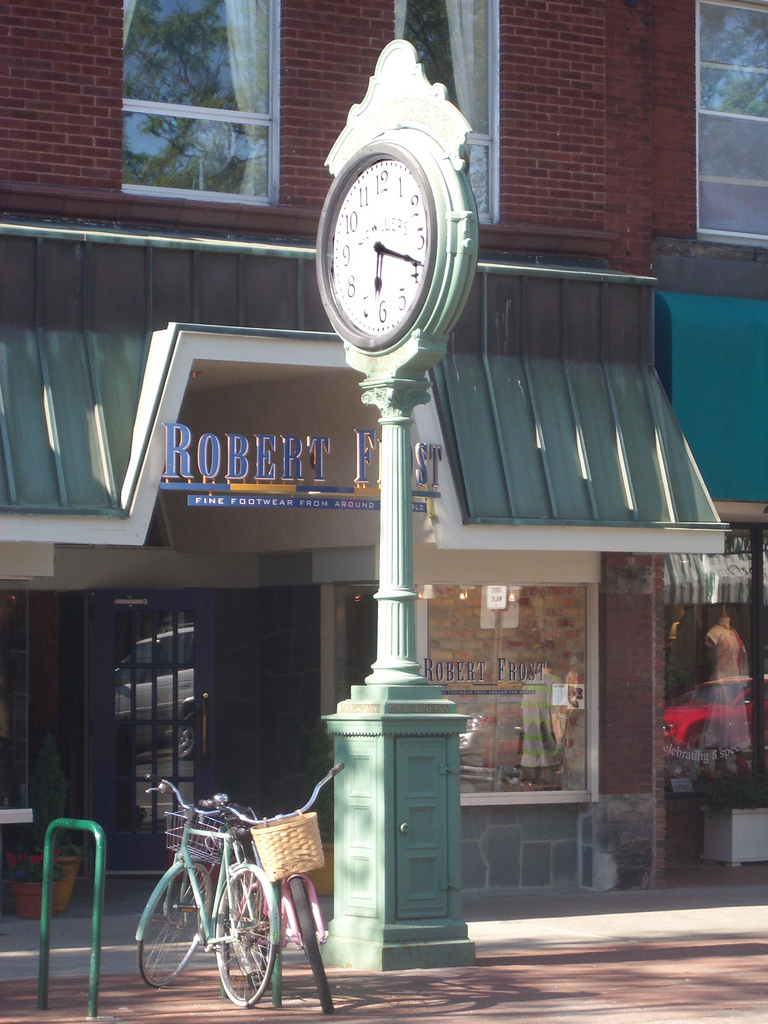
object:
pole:
[369, 413, 425, 671]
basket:
[245, 807, 325, 883]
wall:
[0, 5, 652, 919]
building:
[4, 2, 767, 919]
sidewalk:
[0, 896, 761, 1013]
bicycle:
[198, 755, 349, 1013]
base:
[332, 670, 467, 977]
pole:
[315, 359, 481, 972]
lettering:
[474, 654, 491, 687]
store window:
[415, 580, 592, 805]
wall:
[5, 2, 654, 292]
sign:
[155, 419, 448, 517]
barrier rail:
[32, 814, 108, 1020]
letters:
[352, 424, 379, 484]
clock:
[313, 142, 439, 348]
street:
[0, 906, 764, 1015]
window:
[116, 2, 286, 205]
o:
[196, 425, 223, 480]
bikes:
[129, 766, 285, 1012]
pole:
[309, 22, 482, 981]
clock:
[265, 20, 524, 976]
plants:
[4, 703, 93, 935]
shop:
[0, 203, 702, 940]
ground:
[9, 895, 764, 1016]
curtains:
[222, 0, 276, 202]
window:
[382, 528, 612, 816]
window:
[393, 537, 619, 838]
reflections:
[465, 572, 533, 794]